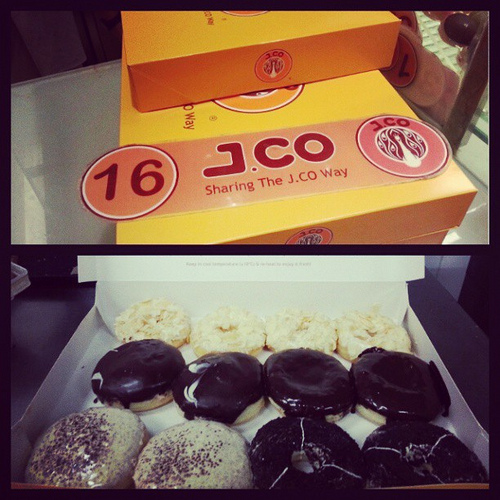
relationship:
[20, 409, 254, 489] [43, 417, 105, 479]
donuts with sprinkles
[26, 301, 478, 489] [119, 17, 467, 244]
donuts in box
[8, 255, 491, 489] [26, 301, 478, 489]
box of donuts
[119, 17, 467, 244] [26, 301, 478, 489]
box of donuts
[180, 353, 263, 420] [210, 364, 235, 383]
chocolate covering hole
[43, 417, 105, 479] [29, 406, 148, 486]
sprinkles on donut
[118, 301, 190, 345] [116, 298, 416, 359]
white donut covering donuts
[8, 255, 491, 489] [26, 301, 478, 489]
box holding donuts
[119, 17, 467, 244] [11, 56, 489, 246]
box on table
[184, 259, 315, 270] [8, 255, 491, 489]
writing inside box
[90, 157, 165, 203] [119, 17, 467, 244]
number 16 on box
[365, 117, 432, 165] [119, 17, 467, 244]
logo on box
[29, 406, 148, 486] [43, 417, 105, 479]
donut with sprinkles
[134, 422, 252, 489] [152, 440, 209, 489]
white donut with sprinkles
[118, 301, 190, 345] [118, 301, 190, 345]
white donut with white donut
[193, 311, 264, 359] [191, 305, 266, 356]
white donut with white donut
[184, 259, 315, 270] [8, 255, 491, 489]
writing on box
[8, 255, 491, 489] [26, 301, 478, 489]
box full of donuts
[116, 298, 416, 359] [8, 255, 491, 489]
donuts in box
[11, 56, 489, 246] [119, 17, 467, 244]
table under box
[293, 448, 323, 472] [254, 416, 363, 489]
hole in donut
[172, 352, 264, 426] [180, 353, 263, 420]
chocolate with chocolate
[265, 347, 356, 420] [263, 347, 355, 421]
donut with donut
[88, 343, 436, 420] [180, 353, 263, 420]
donuts with chocolate